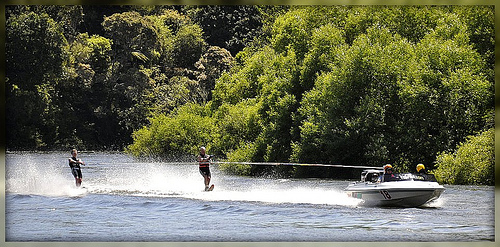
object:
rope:
[87, 161, 384, 171]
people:
[194, 146, 219, 193]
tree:
[424, 127, 498, 186]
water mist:
[4, 146, 448, 207]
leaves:
[254, 47, 320, 115]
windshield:
[383, 172, 435, 183]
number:
[380, 190, 392, 200]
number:
[375, 189, 386, 202]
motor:
[358, 170, 382, 184]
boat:
[340, 168, 448, 209]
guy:
[65, 149, 90, 188]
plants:
[424, 125, 494, 187]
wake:
[5, 152, 493, 242]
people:
[380, 163, 398, 182]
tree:
[427, 127, 492, 186]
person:
[412, 163, 433, 182]